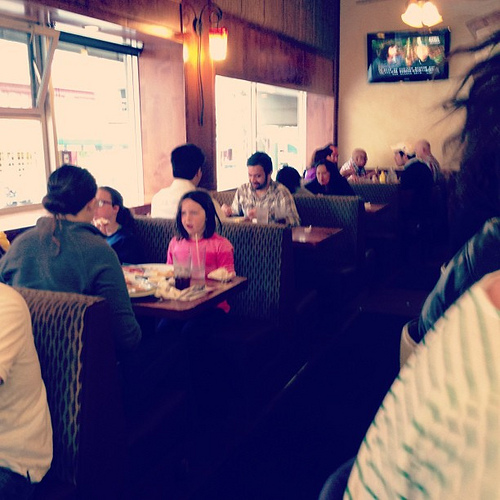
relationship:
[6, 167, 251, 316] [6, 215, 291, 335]
family on booth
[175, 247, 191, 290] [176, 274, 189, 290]
cup have coca cola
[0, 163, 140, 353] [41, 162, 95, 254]
adult has ponytail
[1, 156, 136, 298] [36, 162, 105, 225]
adult has head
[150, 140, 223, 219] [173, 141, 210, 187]
adult has head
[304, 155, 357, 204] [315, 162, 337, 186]
adult has head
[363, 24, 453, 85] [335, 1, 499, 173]
framed picture on wall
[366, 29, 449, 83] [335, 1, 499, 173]
framed picture no a wall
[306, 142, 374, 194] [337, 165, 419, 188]
4 people at a table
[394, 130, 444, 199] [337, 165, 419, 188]
people at a table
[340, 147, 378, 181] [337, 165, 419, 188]
man at a table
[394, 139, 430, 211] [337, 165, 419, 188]
man at a table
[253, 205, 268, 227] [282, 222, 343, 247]
cup on a table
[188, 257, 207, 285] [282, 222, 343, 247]
cup on a table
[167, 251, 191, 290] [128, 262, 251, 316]
cup on a table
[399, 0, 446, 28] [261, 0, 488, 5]
fixture on a ceiling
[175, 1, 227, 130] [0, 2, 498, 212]
fixture on a wall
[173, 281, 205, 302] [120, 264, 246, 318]
silverware on a brown table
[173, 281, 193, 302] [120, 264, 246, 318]
silverware on a brown table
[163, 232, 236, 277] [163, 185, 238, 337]
pink shirt on a little girl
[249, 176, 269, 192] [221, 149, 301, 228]
beard on a guy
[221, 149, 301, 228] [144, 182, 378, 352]
guy in a booth